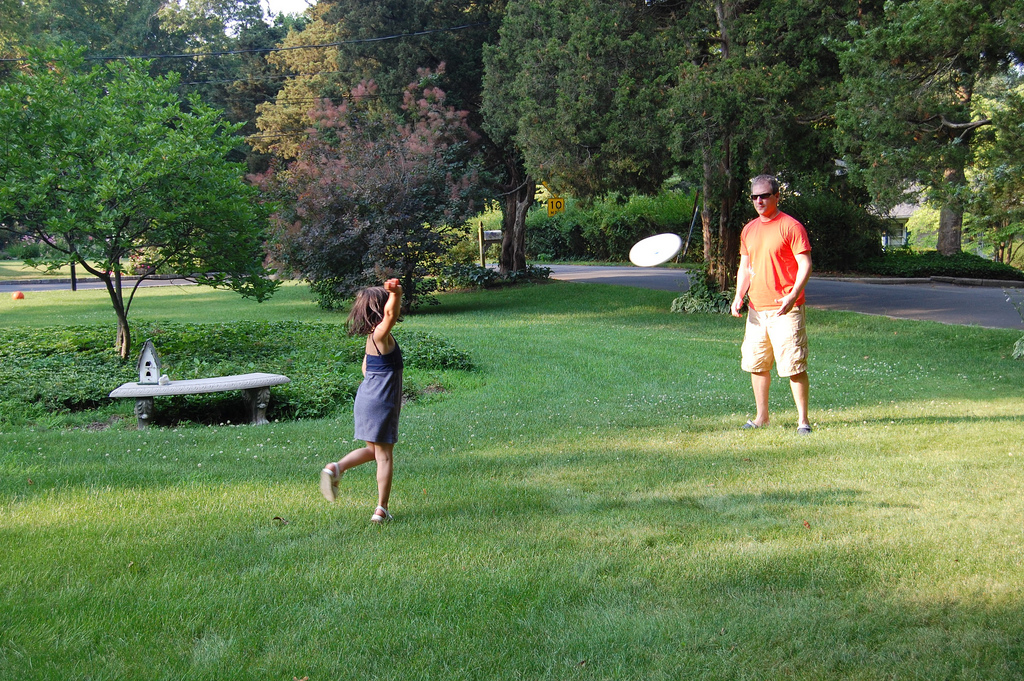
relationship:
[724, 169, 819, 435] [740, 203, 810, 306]
man wearing orange shirt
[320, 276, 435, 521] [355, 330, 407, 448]
kid wearing dress